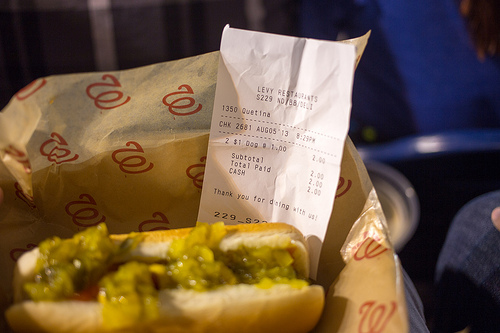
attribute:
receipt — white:
[198, 35, 388, 240]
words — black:
[206, 137, 290, 209]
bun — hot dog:
[2, 214, 329, 330]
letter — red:
[102, 133, 163, 183]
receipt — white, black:
[205, 32, 345, 224]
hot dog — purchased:
[5, 220, 325, 330]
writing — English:
[249, 80, 318, 112]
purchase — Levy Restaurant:
[198, 20, 348, 285]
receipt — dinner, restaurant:
[204, 11, 378, 261]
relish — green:
[118, 227, 292, 294]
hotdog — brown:
[37, 242, 342, 300]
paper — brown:
[4, 43, 376, 238]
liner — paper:
[24, 98, 153, 178]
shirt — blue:
[318, 23, 498, 138]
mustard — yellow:
[141, 219, 329, 309]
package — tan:
[3, 26, 425, 329]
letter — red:
[160, 82, 200, 114]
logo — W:
[163, 82, 202, 116]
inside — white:
[25, 237, 294, 313]